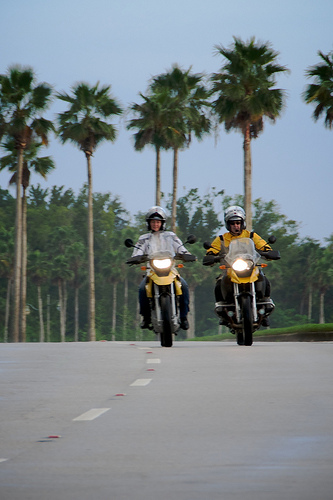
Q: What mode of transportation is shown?
A: Motorcycles.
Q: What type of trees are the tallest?
A: Palm.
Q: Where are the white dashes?
A: Road.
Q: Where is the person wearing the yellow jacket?
A: Motorcycle on the right.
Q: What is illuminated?
A: Motorcycle headlights.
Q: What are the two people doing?
A: Driving motorcycles.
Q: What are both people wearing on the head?
A: Helmet.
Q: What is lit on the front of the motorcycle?
A: Headlights.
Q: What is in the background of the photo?
A: Palm trees.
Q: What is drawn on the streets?
A: White lines.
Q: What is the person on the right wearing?
A: Yellow jacket.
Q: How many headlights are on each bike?
A: One.